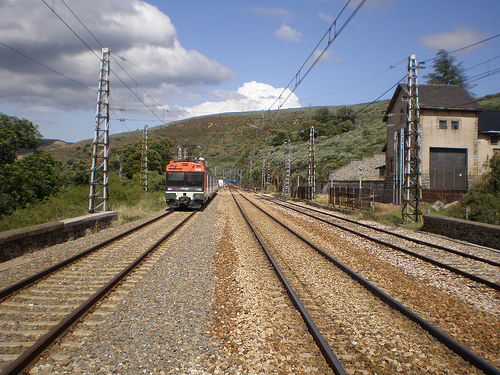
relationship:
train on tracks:
[161, 156, 219, 212] [4, 210, 213, 347]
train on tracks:
[163, 145, 219, 212] [0, 201, 202, 370]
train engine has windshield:
[163, 145, 220, 212] [167, 170, 203, 190]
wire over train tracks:
[0, 4, 478, 137] [0, 210, 499, 371]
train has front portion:
[163, 145, 219, 212] [163, 145, 220, 212]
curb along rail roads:
[53, 211, 497, 272] [0, 210, 499, 371]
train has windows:
[163, 145, 219, 212] [167, 170, 203, 190]